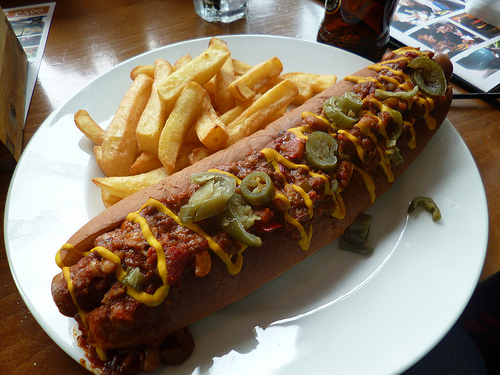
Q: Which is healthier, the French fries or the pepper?
A: The pepper is healthier than the French fries.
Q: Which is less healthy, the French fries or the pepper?
A: The French fries is less healthy than the pepper.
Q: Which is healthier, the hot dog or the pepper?
A: The pepper is healthier than the hot dog.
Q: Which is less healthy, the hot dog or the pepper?
A: The hot dog is less healthy than the pepper.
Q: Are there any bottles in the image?
A: Yes, there is a bottle.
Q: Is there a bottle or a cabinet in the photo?
A: Yes, there is a bottle.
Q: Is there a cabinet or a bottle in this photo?
A: Yes, there is a bottle.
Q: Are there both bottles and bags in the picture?
A: No, there is a bottle but no bags.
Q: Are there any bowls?
A: No, there are no bowls.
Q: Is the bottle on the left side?
A: No, the bottle is on the right of the image.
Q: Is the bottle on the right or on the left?
A: The bottle is on the right of the image.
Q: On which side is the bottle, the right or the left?
A: The bottle is on the right of the image.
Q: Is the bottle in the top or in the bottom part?
A: The bottle is in the top of the image.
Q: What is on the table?
A: The bottle is on the table.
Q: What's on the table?
A: The bottle is on the table.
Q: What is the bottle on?
A: The bottle is on the table.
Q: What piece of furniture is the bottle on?
A: The bottle is on the table.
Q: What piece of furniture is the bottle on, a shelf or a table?
A: The bottle is on a table.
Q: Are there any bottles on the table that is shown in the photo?
A: Yes, there is a bottle on the table.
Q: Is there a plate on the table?
A: No, there is a bottle on the table.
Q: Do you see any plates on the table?
A: No, there is a bottle on the table.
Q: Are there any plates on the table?
A: No, there is a bottle on the table.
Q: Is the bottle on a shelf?
A: No, the bottle is on a table.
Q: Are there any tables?
A: Yes, there is a table.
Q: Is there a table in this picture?
A: Yes, there is a table.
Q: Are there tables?
A: Yes, there is a table.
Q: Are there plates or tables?
A: Yes, there is a table.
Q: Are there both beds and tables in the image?
A: No, there is a table but no beds.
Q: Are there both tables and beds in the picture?
A: No, there is a table but no beds.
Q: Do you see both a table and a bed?
A: No, there is a table but no beds.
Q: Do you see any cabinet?
A: No, there are no cabinets.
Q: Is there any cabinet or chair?
A: No, there are no cabinets or chairs.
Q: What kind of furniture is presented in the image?
A: The furniture is a table.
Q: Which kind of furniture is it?
A: The piece of furniture is a table.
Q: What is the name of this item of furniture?
A: This is a table.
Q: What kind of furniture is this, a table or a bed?
A: This is a table.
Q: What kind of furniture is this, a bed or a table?
A: This is a table.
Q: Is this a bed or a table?
A: This is a table.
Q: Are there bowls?
A: No, there are no bowls.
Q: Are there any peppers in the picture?
A: Yes, there is a pepper.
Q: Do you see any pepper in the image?
A: Yes, there is a pepper.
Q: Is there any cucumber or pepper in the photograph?
A: Yes, there is a pepper.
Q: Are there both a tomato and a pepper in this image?
A: No, there is a pepper but no tomatoes.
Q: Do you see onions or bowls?
A: No, there are no bowls or onions.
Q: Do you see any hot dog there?
A: Yes, there is a hot dog.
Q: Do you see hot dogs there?
A: Yes, there is a hot dog.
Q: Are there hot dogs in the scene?
A: Yes, there is a hot dog.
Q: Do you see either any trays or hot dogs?
A: Yes, there is a hot dog.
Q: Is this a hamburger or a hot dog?
A: This is a hot dog.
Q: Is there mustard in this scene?
A: Yes, there is mustard.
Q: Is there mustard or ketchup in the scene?
A: Yes, there is mustard.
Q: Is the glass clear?
A: Yes, the glass is clear.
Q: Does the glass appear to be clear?
A: Yes, the glass is clear.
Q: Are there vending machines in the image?
A: No, there are no vending machines.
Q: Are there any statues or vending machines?
A: No, there are no vending machines or statues.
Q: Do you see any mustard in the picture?
A: Yes, there is mustard.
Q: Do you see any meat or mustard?
A: Yes, there is mustard.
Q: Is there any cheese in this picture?
A: No, there is no cheese.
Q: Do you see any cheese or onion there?
A: No, there are no cheese or onions.